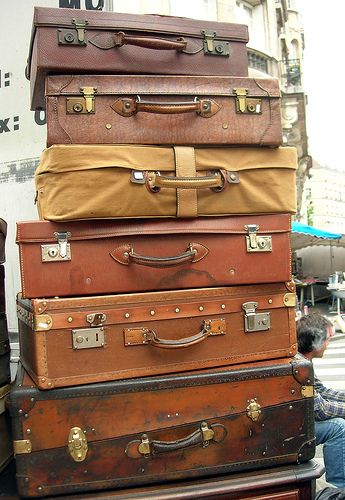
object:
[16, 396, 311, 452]
diaganol line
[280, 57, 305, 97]
balcony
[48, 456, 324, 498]
stand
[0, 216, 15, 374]
table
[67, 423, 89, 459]
gold latch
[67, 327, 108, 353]
metal hook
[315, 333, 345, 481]
railroad track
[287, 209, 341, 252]
canopy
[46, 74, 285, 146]
cases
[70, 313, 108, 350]
lock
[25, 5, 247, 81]
top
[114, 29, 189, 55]
handle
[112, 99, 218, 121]
handle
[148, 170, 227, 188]
handle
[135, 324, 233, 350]
handle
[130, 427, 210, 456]
handle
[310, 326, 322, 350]
grey hair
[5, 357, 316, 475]
brown case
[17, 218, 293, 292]
brown case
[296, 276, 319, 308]
tables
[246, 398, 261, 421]
lock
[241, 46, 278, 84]
balcony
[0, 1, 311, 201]
building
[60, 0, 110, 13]
black letters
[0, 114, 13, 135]
black letters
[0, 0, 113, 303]
wall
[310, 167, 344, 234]
building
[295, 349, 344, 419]
shirt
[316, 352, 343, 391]
lines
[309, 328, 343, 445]
crosswalk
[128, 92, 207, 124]
handle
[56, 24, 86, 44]
lock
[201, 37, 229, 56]
lock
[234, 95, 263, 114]
lock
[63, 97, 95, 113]
lock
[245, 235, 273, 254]
lock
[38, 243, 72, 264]
lock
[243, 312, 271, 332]
lock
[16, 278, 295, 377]
leather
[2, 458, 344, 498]
bottom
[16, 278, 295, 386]
case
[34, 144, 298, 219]
case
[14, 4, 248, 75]
case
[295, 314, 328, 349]
hair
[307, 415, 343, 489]
jeans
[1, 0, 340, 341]
building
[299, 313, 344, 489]
man